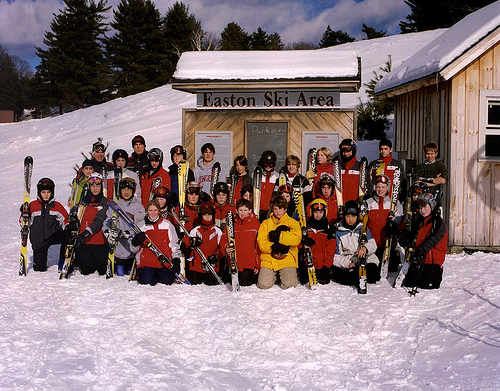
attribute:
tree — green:
[1, 5, 179, 119]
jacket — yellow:
[255, 212, 302, 270]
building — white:
[173, 50, 361, 198]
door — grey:
[249, 122, 286, 167]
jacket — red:
[224, 216, 260, 277]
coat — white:
[332, 220, 375, 270]